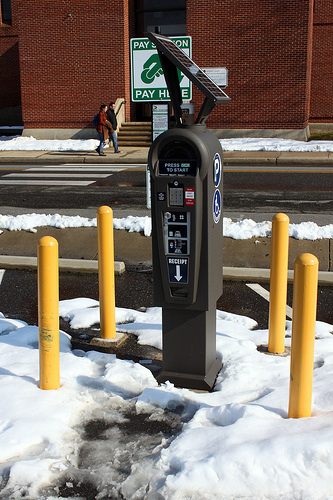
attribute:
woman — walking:
[91, 101, 114, 158]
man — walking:
[106, 101, 121, 154]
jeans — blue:
[108, 132, 122, 155]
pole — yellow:
[35, 234, 64, 394]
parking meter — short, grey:
[145, 26, 231, 393]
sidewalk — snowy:
[2, 208, 331, 280]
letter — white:
[135, 88, 143, 99]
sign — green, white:
[126, 33, 192, 101]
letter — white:
[141, 88, 148, 102]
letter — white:
[158, 88, 167, 99]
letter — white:
[134, 41, 139, 50]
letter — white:
[139, 40, 146, 50]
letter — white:
[180, 86, 190, 99]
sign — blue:
[210, 154, 224, 187]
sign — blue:
[210, 189, 224, 225]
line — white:
[2, 178, 97, 189]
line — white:
[3, 168, 115, 181]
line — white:
[29, 162, 126, 176]